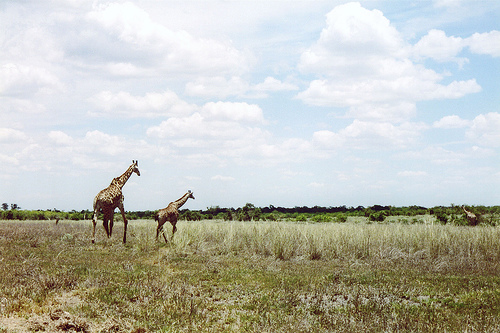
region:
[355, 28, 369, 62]
section of white cloud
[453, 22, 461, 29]
section of the blue sky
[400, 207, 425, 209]
section of a bush plantation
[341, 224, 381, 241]
section of a grass plantation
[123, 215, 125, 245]
front leg of a giraffe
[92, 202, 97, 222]
tail of a giraffe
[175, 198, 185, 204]
neck of a giraffe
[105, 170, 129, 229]
a giraffe in a grass plantation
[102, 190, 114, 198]
back of a giraffe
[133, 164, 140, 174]
head of a giraffe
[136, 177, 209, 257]
a young giraffe walking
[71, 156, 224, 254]
a pair of giraffes on the move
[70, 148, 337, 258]
giraffes on a grassy plain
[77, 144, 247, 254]
giraffes headed toward trees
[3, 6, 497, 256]
more clouds than blue sky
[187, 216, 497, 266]
a wall of dried grasses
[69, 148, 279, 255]
moving to a place with leaves on trees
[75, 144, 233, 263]
giraffes headed away from the camera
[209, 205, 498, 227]
trees and greener grass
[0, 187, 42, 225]
couples of taller trees on the left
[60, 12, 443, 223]
sky is blue and white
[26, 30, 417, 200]
sky is blue and white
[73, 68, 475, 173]
sky is blue and white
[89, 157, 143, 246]
large giraffe walking on grass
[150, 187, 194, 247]
medium size giraffe walking on grass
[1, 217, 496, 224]
horizon line in photograph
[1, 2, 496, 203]
sky is partly cloudy but bright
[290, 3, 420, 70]
one of many clouds in the sky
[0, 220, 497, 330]
large grass field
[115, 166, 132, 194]
neck of giraffe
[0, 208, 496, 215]
taller shrubs in the background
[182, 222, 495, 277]
area of taller grass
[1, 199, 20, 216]
taller trees in background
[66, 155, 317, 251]
two giraffes walking on grasslands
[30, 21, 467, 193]
blue sky with puffy white clouds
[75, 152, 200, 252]
taller giraffe looking at smaller one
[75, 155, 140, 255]
legs together between splayed legs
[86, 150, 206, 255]
younger giraffe headed in a different direction than older giraffe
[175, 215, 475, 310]
taller grasses in back of dried ground and weeds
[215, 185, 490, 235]
greener growth behind tall grasses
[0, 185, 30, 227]
two trees taller than other growth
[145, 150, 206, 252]
giraffe with head lowered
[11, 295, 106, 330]
patch of dried and sandy soil